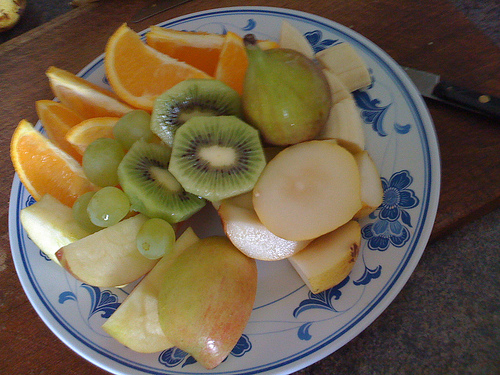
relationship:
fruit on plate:
[10, 23, 378, 375] [384, 127, 451, 299]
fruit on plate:
[10, 23, 378, 375] [29, 25, 446, 373]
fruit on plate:
[10, 23, 378, 375] [375, 112, 430, 181]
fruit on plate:
[10, 23, 378, 375] [3, 3, 448, 373]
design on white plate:
[329, 129, 450, 297] [37, 17, 412, 352]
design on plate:
[388, 70, 449, 182] [349, 150, 431, 278]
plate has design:
[3, 3, 448, 373] [352, 168, 418, 258]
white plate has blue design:
[336, 41, 448, 262] [375, 168, 412, 242]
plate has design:
[3, 3, 448, 373] [289, 272, 366, 339]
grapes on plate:
[66, 105, 179, 262] [3, 3, 448, 373]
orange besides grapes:
[98, 20, 211, 100] [66, 105, 179, 262]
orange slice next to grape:
[41, 62, 134, 118] [112, 105, 154, 150]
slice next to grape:
[110, 37, 182, 87] [81, 113, 159, 197]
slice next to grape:
[209, 30, 253, 108] [232, 26, 334, 137]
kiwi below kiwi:
[167, 114, 267, 199] [147, 77, 243, 145]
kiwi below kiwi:
[119, 138, 204, 221] [147, 77, 243, 145]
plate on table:
[3, 3, 448, 373] [369, 41, 491, 232]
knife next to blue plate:
[398, 54, 498, 145] [386, 175, 433, 254]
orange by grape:
[98, 20, 211, 100] [79, 135, 126, 187]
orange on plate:
[98, 20, 211, 100] [3, 3, 448, 373]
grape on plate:
[79, 135, 126, 187] [3, 3, 448, 373]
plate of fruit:
[3, 3, 448, 373] [13, 23, 385, 356]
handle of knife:
[430, 74, 484, 117] [410, 67, 499, 112]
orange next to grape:
[22, 88, 102, 159] [79, 135, 126, 187]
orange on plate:
[22, 88, 102, 159] [3, 3, 448, 373]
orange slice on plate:
[63, 115, 159, 152] [3, 3, 448, 373]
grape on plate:
[110, 108, 154, 149] [3, 3, 448, 373]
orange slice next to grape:
[63, 115, 159, 152] [79, 135, 126, 187]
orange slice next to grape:
[63, 115, 159, 152] [110, 108, 154, 149]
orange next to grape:
[98, 20, 211, 100] [81, 140, 134, 181]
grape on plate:
[81, 140, 134, 181] [3, 3, 448, 373]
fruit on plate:
[13, 23, 385, 356] [3, 3, 448, 373]